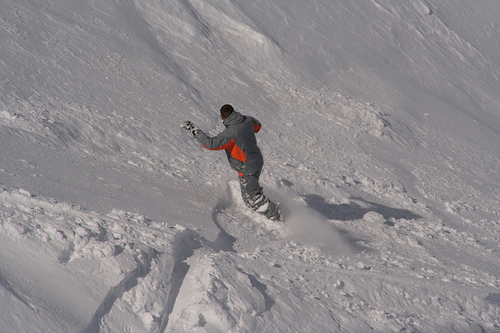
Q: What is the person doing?
A: Snowboarding.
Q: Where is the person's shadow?
A: On the snow.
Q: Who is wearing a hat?
A: Snowboarder.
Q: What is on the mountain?
A: Snow.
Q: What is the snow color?
A: White.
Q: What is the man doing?
A: Snowboarding.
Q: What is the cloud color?
A: White.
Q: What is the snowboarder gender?
A: Male.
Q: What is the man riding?
A: Snowboard.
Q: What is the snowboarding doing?
A: Riding.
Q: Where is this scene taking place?
A: On a ski slope.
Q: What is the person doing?
A: Snowboarding.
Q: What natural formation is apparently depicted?
A: A mountain.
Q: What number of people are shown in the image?
A: One.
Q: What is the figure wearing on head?
A: A knit hat.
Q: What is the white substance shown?
A: Snow.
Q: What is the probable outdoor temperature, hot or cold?
A: Cold.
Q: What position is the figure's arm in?
A: Raised and bent.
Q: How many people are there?
A: 1.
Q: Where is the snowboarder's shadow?
A: On ground.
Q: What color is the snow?
A: White.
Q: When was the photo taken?
A: Daytime.